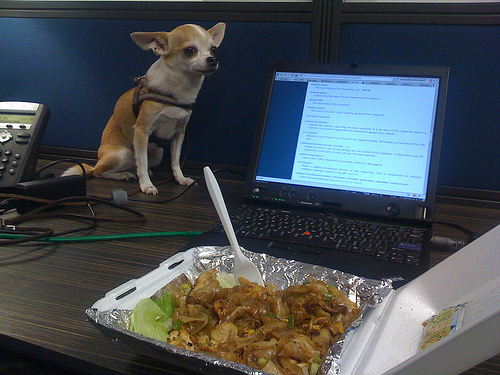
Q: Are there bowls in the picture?
A: No, there are no bowls.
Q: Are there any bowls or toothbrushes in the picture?
A: No, there are no bowls or toothbrushes.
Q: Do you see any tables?
A: Yes, there is a table.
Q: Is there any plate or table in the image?
A: Yes, there is a table.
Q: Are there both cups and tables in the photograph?
A: No, there is a table but no cups.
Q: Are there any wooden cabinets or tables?
A: Yes, there is a wood table.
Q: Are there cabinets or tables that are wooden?
A: Yes, the table is wooden.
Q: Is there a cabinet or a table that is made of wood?
A: Yes, the table is made of wood.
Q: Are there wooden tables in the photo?
A: Yes, there is a wood table.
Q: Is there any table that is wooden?
A: Yes, there is a table that is wooden.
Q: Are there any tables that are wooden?
A: Yes, there is a table that is wooden.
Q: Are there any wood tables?
A: Yes, there is a table that is made of wood.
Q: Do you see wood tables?
A: Yes, there is a table that is made of wood.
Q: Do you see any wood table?
A: Yes, there is a table that is made of wood.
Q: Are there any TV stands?
A: No, there are no TV stands.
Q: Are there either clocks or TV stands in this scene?
A: No, there are no TV stands or clocks.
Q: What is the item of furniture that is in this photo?
A: The piece of furniture is a table.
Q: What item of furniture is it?
A: The piece of furniture is a table.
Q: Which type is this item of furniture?
A: This is a table.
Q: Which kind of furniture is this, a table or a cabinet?
A: This is a table.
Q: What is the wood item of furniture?
A: The piece of furniture is a table.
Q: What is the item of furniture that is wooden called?
A: The piece of furniture is a table.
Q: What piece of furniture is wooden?
A: The piece of furniture is a table.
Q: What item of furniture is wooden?
A: The piece of furniture is a table.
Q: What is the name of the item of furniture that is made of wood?
A: The piece of furniture is a table.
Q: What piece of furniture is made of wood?
A: The piece of furniture is a table.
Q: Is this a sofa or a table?
A: This is a table.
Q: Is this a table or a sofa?
A: This is a table.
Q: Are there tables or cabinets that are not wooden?
A: No, there is a table but it is wooden.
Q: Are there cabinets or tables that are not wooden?
A: No, there is a table but it is wooden.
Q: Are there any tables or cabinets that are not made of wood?
A: No, there is a table but it is made of wood.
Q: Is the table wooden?
A: Yes, the table is wooden.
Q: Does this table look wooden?
A: Yes, the table is wooden.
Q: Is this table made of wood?
A: Yes, the table is made of wood.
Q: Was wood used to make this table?
A: Yes, the table is made of wood.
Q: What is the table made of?
A: The table is made of wood.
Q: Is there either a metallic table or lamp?
A: No, there is a table but it is wooden.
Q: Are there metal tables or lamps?
A: No, there is a table but it is wooden.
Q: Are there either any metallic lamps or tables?
A: No, there is a table but it is wooden.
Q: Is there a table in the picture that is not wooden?
A: No, there is a table but it is wooden.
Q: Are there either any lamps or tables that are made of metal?
A: No, there is a table but it is made of wood.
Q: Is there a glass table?
A: No, there is a table but it is made of wood.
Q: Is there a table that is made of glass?
A: No, there is a table but it is made of wood.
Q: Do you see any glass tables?
A: No, there is a table but it is made of wood.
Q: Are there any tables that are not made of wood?
A: No, there is a table but it is made of wood.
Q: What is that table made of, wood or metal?
A: The table is made of wood.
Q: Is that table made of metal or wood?
A: The table is made of wood.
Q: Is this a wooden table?
A: Yes, this is a wooden table.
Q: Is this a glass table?
A: No, this is a wooden table.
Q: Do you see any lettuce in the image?
A: Yes, there is lettuce.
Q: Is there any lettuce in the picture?
A: Yes, there is lettuce.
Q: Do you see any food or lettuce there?
A: Yes, there is lettuce.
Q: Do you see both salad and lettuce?
A: No, there is lettuce but no salad.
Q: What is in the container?
A: The lettuce is in the container.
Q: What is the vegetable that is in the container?
A: The vegetable is lettuce.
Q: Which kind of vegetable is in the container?
A: The vegetable is lettuce.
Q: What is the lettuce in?
A: The lettuce is in the container.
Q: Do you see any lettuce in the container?
A: Yes, there is lettuce in the container.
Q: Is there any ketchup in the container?
A: No, there is lettuce in the container.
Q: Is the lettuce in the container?
A: Yes, the lettuce is in the container.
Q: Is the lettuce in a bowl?
A: No, the lettuce is in the container.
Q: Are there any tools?
A: No, there are no tools.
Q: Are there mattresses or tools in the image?
A: No, there are no tools or mattresses.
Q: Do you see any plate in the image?
A: No, there are no plates.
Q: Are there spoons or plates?
A: No, there are no plates or spoons.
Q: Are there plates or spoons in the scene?
A: No, there are no plates or spoons.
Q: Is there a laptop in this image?
A: Yes, there is a laptop.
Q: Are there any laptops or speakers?
A: Yes, there is a laptop.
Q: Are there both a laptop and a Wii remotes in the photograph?
A: No, there is a laptop but no Wii controllers.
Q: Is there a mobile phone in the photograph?
A: No, there are no cell phones.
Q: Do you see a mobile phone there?
A: No, there are no cell phones.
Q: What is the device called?
A: The device is a laptop.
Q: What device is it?
A: The device is a laptop.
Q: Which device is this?
A: That is a laptop.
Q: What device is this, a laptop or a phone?
A: That is a laptop.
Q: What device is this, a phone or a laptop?
A: That is a laptop.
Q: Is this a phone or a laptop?
A: This is a laptop.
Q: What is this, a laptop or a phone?
A: This is a laptop.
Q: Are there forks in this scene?
A: Yes, there is a fork.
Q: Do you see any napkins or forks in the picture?
A: Yes, there is a fork.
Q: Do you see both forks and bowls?
A: No, there is a fork but no bowls.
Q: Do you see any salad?
A: No, there is no salad.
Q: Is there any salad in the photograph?
A: No, there is no salad.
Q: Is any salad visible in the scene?
A: No, there is no salad.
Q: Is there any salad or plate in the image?
A: No, there are no salad or plates.